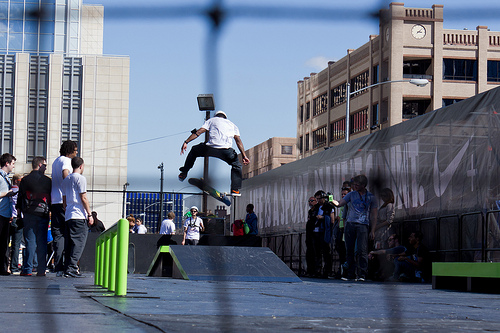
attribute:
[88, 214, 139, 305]
pole — green, lime green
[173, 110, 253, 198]
man — young, skateboarding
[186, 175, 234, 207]
skateboard — black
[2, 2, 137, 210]
building — tan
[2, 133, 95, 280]
people — watching, standing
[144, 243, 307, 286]
ramp — black, low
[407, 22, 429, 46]
clock — white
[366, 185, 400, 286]
woman — leaning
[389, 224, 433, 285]
man — sitting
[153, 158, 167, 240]
light post — tall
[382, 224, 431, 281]
two people — sitting